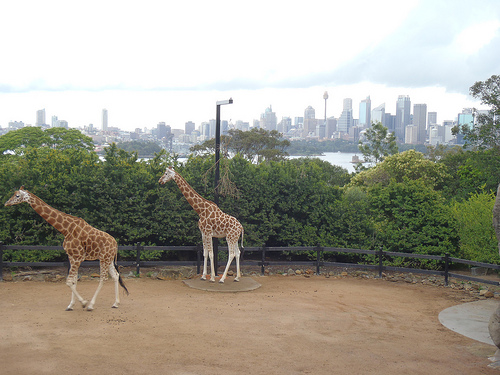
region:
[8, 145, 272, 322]
two giraffes in a pen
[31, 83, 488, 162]
a large skyline to a downtown city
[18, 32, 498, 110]
a large white cloud in the sky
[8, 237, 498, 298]
a short gray and black fence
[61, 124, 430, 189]
water in front of the city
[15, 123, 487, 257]
many trees behind fence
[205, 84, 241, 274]
a black metal pole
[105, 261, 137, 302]
long black hairs on tail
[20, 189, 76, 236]
long neck of giraffe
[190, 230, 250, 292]
long white legs of giraffe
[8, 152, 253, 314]
two giraffes in the zoo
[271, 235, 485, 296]
black fence surrounding giraffes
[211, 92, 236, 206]
light on a pole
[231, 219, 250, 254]
tail on a giraffe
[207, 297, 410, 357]
dirt ground by the giraffe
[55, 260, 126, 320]
legs of a giraffe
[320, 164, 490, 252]
green bushes behind giraffe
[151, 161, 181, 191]
head of a giraffe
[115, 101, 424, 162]
skyline of a city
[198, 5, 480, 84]
cloudy sky in the distance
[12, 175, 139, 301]
TALL GIRAFFE STANDING IN ZOO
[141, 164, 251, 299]
TALL GIRAFFE STANDING IN ZOO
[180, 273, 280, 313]
ROUND CONCRETE PLATFORM UNDER GIRAFFE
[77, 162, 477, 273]
GREEN TREES GROWING AROUND PEN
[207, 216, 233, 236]
YELLOW AND BROWN SPOTS ON GIRAFFE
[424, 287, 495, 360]
CONCRETE SIDE WALK ON RIGHT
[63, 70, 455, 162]
CITY SKYLINE IN DISTANCE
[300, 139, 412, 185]
BODY OF WATER BETWEEN GIRAFFES AND CITY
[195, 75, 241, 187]
METAL POLE BY PEN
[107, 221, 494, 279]
SMALL BLACK FENCE AROUND PEN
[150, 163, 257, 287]
giraffe on right facing left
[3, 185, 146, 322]
giraffe on left facing left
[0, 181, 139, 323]
giraffe on left walking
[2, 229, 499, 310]
dark gray wooden fence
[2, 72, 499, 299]
grove of trees beyond giraffe pen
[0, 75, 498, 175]
cityscape in distant background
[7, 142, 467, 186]
body of water beyond trees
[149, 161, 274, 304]
giraffe standing on circle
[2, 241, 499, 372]
sandy dirt in giraffe pen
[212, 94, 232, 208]
long narrow metal pole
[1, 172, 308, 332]
two giraffes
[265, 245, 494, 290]
fence next to trees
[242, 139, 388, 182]
water on the other side of trees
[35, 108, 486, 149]
city on the other side of the water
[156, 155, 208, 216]
giraffes have long necks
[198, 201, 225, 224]
giraffes are brown and white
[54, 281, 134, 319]
giraffe's legs are white from the knee down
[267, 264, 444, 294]
rocks at the bottom of fence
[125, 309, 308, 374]
dirt in the exhibit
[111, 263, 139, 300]
brown bushy hair at the end of the tail